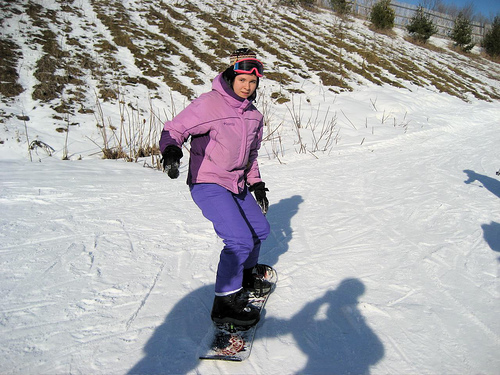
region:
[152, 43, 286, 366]
Woman standing on snowboard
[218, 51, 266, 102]
Woman with pink snow goggles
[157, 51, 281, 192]
Woman wearing pink and purple coat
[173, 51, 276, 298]
Woman wearing purple pants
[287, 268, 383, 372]
Shadow of photographer on snow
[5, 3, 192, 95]
Grassy slope with patchy snow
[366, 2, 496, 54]
Small trees in background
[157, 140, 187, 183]
Black glove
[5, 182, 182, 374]
Ski tracks in snow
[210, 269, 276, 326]
Black snow boots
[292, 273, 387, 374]
the shadow of someone taking a picture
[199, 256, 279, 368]
a small snowboard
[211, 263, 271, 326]
a pair of black kids snowboard boots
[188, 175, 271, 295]
a pair of purple girls pants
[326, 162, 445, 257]
a patch of white snow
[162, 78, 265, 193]
a young girls light purple jacket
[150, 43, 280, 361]
a young girl on a snowboard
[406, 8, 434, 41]
a small green tree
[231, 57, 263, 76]
a pair of pink snow goggles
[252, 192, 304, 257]
a young girls shadow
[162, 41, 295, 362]
woman standing on snowboard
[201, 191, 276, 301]
purple pants of woman on snowboard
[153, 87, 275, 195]
pink coat of woman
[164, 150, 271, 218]
black gloves of woman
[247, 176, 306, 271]
snowboarder's shadow on the snow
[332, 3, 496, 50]
trees lining the mountainside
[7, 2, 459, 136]
moutain covered with patchy snow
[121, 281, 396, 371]
shadows on either side of snowboarder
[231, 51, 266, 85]
pink goggles of girl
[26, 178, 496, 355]
tracks in the snow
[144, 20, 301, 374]
a woman wearing purple pants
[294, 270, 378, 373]
a shadow on the snow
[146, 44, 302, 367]
a woman wearing a lavender coat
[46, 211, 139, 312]
tracks in the snow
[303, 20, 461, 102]
brown grass on the hill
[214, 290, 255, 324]
black snow boots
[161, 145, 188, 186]
black gloves on a hand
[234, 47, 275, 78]
pink snow goggles on a head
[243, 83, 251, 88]
nose on a face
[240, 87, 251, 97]
pinks lips in a face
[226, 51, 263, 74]
a pair of ski goggles.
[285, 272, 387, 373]
a shadow cast on the snow.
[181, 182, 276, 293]
a pair of purple pants.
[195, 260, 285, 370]
a snowboard on the ground.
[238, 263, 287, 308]
a left foot shoe.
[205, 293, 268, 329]
a right foot shoe.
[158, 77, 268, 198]
a pink snow jacket.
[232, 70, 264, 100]
the face of a young woman.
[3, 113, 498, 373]
snow covered ski slope.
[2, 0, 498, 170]
a snow covered hillside.